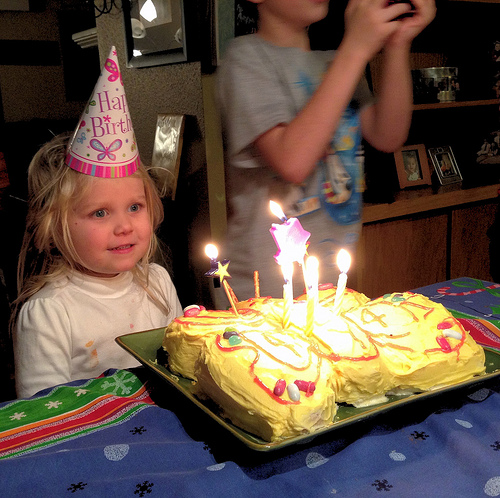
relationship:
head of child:
[53, 124, 195, 258] [6, 132, 186, 402]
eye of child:
[75, 191, 169, 234] [6, 132, 186, 402]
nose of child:
[94, 206, 164, 254] [6, 132, 186, 402]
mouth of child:
[95, 223, 153, 277] [6, 132, 186, 402]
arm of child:
[34, 310, 93, 418] [6, 132, 186, 402]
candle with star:
[182, 163, 381, 358] [209, 239, 245, 305]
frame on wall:
[417, 112, 466, 187] [139, 71, 190, 137]